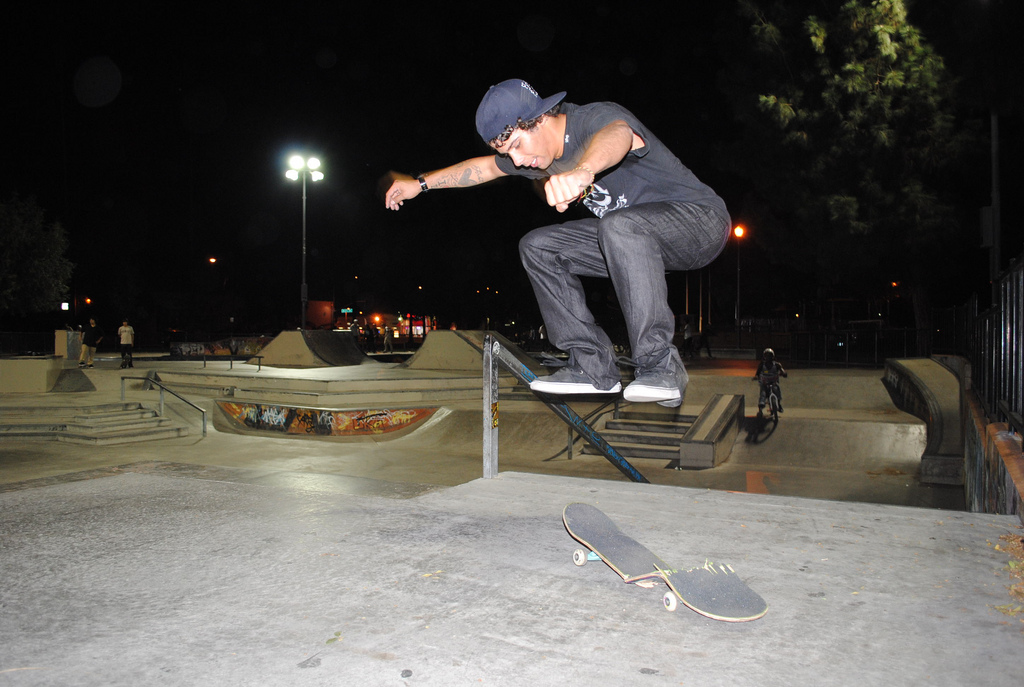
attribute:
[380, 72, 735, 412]
man — mid-air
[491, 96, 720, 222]
shirt — black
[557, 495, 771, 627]
skateboard — broken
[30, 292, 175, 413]
guys — standing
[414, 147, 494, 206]
ink — black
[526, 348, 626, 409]
shoe — black, white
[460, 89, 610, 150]
hat — blue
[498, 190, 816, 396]
pants — dark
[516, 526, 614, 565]
wheel — attached